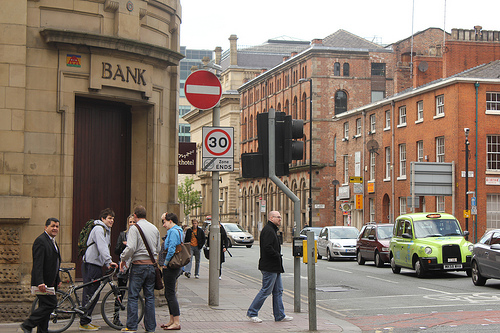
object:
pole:
[208, 171, 221, 305]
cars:
[468, 229, 500, 285]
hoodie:
[83, 219, 114, 266]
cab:
[388, 211, 472, 278]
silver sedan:
[318, 226, 359, 262]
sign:
[183, 69, 222, 111]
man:
[246, 211, 295, 323]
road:
[243, 245, 495, 301]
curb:
[322, 310, 362, 333]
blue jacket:
[162, 226, 185, 266]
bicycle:
[28, 261, 147, 332]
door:
[71, 92, 131, 279]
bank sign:
[102, 61, 146, 85]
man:
[75, 208, 117, 330]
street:
[0, 0, 500, 333]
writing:
[216, 164, 232, 169]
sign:
[202, 126, 235, 172]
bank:
[0, 0, 180, 291]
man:
[16, 217, 61, 332]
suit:
[20, 231, 62, 331]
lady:
[157, 212, 191, 330]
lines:
[365, 274, 401, 284]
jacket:
[258, 220, 285, 273]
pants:
[246, 271, 285, 320]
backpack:
[78, 220, 93, 255]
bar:
[186, 85, 220, 95]